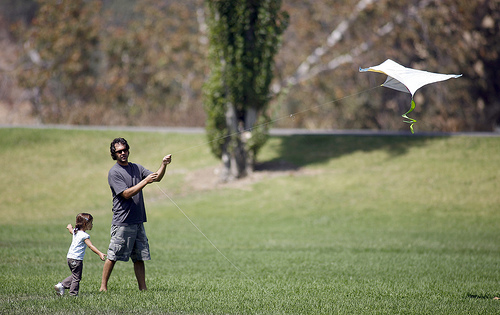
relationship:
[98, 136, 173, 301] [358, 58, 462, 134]
man flying kite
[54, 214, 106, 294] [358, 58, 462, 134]
girl flying kite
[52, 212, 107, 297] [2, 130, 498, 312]
girl on grass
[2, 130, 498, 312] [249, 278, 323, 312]
grass of patch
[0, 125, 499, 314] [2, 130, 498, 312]
patch of grass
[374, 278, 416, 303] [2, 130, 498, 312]
patch of grass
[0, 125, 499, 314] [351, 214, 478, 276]
patch of grass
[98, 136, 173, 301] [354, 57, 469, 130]
man flying kite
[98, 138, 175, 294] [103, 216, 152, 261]
man wearing shorts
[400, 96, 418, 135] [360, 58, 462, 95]
ribbon on kite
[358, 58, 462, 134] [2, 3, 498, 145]
kite in sky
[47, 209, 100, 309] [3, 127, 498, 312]
kid in field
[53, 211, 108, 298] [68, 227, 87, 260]
kid wearing white shirt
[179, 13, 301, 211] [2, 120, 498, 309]
tree in park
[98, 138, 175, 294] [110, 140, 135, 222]
man wearing shirt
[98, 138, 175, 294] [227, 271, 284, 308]
man standing in grass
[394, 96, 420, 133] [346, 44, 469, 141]
ribbon hanging from kite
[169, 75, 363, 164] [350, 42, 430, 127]
string hanging off kite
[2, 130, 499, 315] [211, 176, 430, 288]
grass on ground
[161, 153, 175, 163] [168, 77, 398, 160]
fingers around string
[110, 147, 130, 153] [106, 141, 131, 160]
sunglasses on face